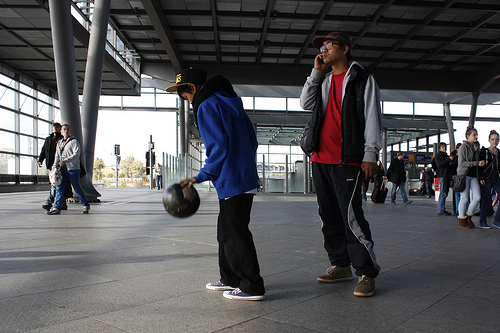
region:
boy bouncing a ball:
[155, 47, 282, 292]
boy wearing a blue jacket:
[147, 51, 269, 288]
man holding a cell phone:
[301, 23, 408, 279]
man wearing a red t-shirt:
[291, 32, 398, 287]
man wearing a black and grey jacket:
[286, 23, 407, 266]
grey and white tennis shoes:
[188, 256, 283, 308]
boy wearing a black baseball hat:
[157, 53, 271, 316]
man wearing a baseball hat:
[294, 22, 407, 299]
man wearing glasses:
[294, 21, 409, 295]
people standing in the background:
[389, 82, 498, 229]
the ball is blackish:
[149, 166, 206, 234]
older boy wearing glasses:
[298, 22, 350, 76]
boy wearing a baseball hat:
[152, 62, 207, 99]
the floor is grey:
[42, 224, 187, 329]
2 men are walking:
[10, 108, 115, 237]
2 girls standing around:
[449, 115, 497, 234]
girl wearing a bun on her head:
[457, 115, 477, 131]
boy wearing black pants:
[194, 182, 270, 319]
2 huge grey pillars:
[12, 8, 128, 228]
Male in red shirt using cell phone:
[301, 28, 379, 191]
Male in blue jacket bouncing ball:
[150, 53, 267, 298]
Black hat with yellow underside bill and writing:
[159, 64, 211, 91]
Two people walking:
[42, 119, 97, 214]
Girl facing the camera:
[480, 129, 498, 180]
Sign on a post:
[110, 140, 124, 188]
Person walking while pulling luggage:
[371, 143, 410, 205]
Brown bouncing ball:
[161, 177, 201, 219]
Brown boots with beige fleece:
[457, 211, 477, 231]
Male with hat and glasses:
[311, 29, 353, 74]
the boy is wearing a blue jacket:
[191, 90, 262, 201]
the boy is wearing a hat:
[165, 65, 196, 87]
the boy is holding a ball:
[163, 181, 201, 218]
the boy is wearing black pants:
[214, 192, 256, 302]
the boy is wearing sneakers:
[204, 281, 264, 301]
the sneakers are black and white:
[206, 279, 265, 301]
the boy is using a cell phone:
[309, 34, 356, 78]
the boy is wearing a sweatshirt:
[302, 61, 382, 163]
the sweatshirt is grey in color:
[299, 66, 391, 167]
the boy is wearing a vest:
[303, 63, 382, 161]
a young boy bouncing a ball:
[160, 65, 270, 303]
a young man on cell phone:
[296, 32, 385, 299]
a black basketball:
[158, 179, 199, 219]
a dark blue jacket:
[190, 92, 261, 201]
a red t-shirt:
[307, 68, 344, 163]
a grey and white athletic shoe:
[222, 287, 263, 299]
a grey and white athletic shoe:
[202, 279, 229, 292]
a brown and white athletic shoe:
[350, 274, 375, 297]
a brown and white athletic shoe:
[313, 264, 352, 281]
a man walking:
[44, 122, 93, 217]